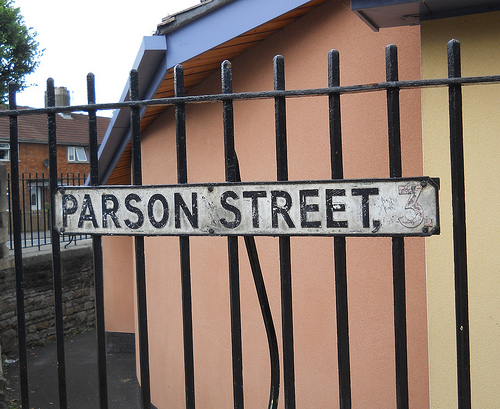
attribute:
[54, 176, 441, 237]
sign — white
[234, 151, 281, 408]
bar — bent, black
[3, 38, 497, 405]
fence — iron, black, metal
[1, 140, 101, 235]
wall — brick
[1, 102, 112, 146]
roof — brown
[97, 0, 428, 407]
building — pink, peach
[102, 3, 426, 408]
wall — peach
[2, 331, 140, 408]
ground — grey, paved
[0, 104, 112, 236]
building — brick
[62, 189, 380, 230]
writing — black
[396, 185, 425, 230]
number — faded, three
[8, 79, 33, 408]
rod — vertical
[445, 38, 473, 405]
rod — vertical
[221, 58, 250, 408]
rod — vertical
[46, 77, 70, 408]
rod — vertical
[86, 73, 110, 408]
rod — vertical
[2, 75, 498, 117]
pole — horizontal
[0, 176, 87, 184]
pole — horizontal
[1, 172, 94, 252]
fence — metal, black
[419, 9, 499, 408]
wall — tan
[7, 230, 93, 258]
ground — paved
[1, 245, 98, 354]
wall — rock